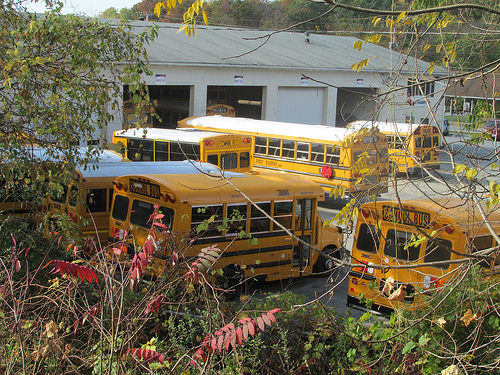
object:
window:
[422, 236, 451, 270]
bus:
[110, 171, 342, 298]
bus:
[346, 197, 498, 322]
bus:
[347, 119, 439, 176]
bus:
[110, 126, 250, 174]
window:
[219, 153, 240, 168]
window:
[420, 137, 431, 149]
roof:
[441, 66, 498, 102]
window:
[310, 143, 321, 163]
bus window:
[357, 221, 379, 255]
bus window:
[424, 236, 451, 270]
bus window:
[189, 203, 226, 238]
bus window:
[271, 197, 295, 231]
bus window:
[110, 193, 130, 222]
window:
[253, 137, 267, 154]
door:
[290, 197, 315, 270]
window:
[274, 198, 293, 229]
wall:
[249, 70, 282, 85]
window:
[323, 144, 337, 165]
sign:
[321, 164, 332, 176]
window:
[404, 78, 413, 97]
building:
[0, 12, 451, 147]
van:
[475, 118, 497, 140]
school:
[2, 0, 499, 308]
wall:
[191, 86, 206, 116]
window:
[295, 141, 310, 161]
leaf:
[214, 333, 223, 350]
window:
[265, 136, 280, 156]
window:
[308, 143, 327, 166]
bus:
[173, 113, 387, 202]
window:
[355, 220, 381, 254]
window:
[385, 225, 420, 263]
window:
[468, 234, 493, 274]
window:
[190, 206, 222, 236]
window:
[225, 205, 249, 235]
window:
[245, 203, 274, 233]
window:
[152, 207, 177, 233]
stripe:
[131, 181, 144, 187]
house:
[445, 64, 498, 136]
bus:
[109, 175, 347, 292]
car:
[444, 120, 449, 134]